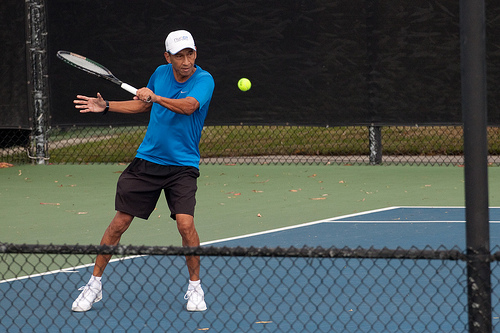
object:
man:
[66, 27, 218, 313]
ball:
[236, 77, 252, 92]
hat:
[163, 29, 199, 56]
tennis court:
[0, 164, 500, 333]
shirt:
[133, 63, 217, 171]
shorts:
[113, 156, 202, 221]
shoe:
[182, 283, 209, 312]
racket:
[53, 49, 152, 103]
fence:
[0, 241, 500, 333]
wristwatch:
[101, 99, 109, 116]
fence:
[0, 0, 500, 168]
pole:
[457, 0, 495, 333]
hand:
[132, 86, 158, 104]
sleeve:
[185, 70, 217, 112]